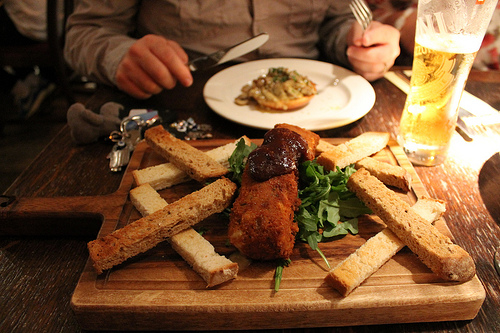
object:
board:
[67, 132, 487, 329]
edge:
[67, 278, 137, 323]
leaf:
[303, 168, 344, 198]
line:
[0, 148, 66, 194]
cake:
[229, 122, 319, 260]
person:
[61, 0, 403, 99]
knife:
[180, 31, 269, 73]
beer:
[395, 52, 477, 148]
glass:
[398, 1, 495, 146]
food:
[233, 65, 317, 110]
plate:
[201, 55, 381, 133]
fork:
[348, 1, 376, 32]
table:
[0, 65, 499, 332]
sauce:
[244, 126, 308, 181]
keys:
[105, 105, 215, 171]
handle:
[0, 194, 113, 236]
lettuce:
[227, 136, 348, 243]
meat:
[230, 122, 319, 261]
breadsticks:
[84, 122, 243, 288]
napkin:
[399, 66, 482, 136]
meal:
[86, 122, 477, 296]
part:
[135, 274, 170, 289]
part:
[389, 270, 419, 303]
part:
[256, 205, 287, 242]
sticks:
[87, 177, 240, 275]